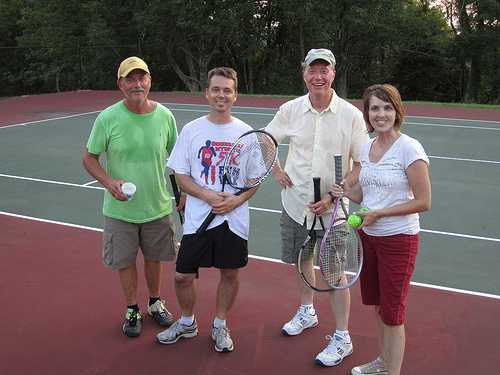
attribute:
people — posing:
[82, 47, 431, 373]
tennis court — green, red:
[0, 90, 499, 374]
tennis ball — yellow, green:
[346, 213, 362, 228]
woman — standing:
[332, 82, 432, 374]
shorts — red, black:
[357, 225, 420, 326]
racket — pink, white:
[318, 152, 365, 291]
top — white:
[358, 134, 428, 238]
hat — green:
[304, 47, 336, 67]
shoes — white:
[282, 306, 354, 366]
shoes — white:
[157, 317, 237, 353]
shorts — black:
[176, 220, 249, 267]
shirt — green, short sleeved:
[86, 98, 180, 225]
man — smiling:
[261, 47, 370, 367]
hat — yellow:
[116, 56, 150, 80]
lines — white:
[1, 100, 499, 300]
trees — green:
[0, 1, 498, 106]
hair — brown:
[361, 82, 405, 135]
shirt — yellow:
[266, 87, 371, 230]